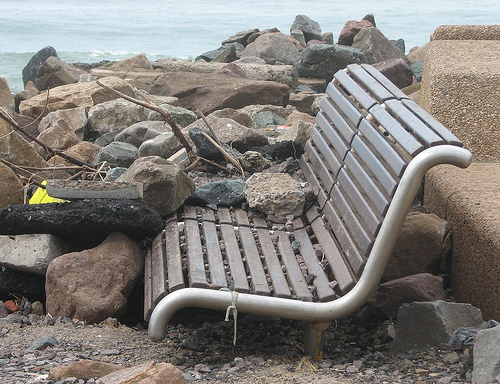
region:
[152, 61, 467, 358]
bench under the rocks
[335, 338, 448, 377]
rocks on ground near bench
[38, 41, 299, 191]
large rocks on top of bench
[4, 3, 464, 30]
water in the distance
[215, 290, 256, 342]
tie on the bench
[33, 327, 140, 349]
dirt on the ground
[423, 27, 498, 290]
block of concrete behind bench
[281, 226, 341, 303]
smaller rocks on seat of bench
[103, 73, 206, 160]
branch of tree in rocks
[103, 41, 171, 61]
white water in body of water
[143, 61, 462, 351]
a metal bench by a ocean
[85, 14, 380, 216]
several large rocks piled together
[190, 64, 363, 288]
several rocks on a bench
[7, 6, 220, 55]
a body of water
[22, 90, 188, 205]
sticks and twigs in a pile of rocks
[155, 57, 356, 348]
rocks covering a metal bench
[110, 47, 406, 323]
rocks on top of a bench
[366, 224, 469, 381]
rocks behind a bench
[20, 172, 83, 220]
a yellow piece of paper on rocks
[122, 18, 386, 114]
large boulders next to the water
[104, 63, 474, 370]
bench on the rocks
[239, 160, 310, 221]
large rock on the bench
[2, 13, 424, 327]
sevearl rocks along the shoreline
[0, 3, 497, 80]
body of water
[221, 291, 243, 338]
string hanging off the bench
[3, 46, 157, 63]
small ripple in the water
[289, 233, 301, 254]
tiny rock on the bench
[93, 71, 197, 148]
thick stick jutting out of the rocks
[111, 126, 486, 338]
metal along the side of the bench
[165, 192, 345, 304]
seat of the bench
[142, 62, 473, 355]
Wooden and metal park bench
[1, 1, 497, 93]
Calm sea water in the background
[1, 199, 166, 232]
Piece of black asphalt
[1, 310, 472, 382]
Gravel underneath park bench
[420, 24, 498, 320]
Pebble stoned wall behind bench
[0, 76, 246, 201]
Twigs stuck in boulders and debris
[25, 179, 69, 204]
Yellow debris stuck in rocks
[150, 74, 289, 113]
One large boulder in the middle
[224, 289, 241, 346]
Scrap of rope tied to bench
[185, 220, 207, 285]
Wooden bar on park bench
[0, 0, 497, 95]
THIS IS THE WATER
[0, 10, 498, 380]
THESE ARE BIG ROCKS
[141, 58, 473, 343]
HERE IS A BENCH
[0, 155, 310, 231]
HERE ARE SOME ROCKS ON THE BENCH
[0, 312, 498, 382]
HERE IS SOME ROCKS IN THE DIRT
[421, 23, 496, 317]
HERE ARE SOME STEPS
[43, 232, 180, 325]
A ROCK IN FRONT OF THE BENCH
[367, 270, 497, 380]
THESE ARE ROCKS BEHIND THE BENCH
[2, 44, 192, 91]
THE WAVES IN THE WATER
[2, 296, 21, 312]
THIS IS A RED OBJECT